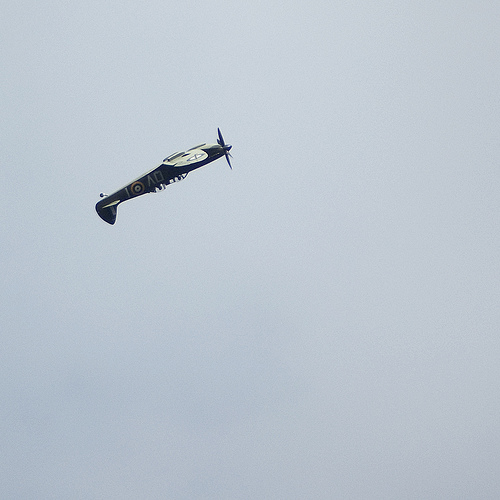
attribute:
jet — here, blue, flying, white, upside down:
[94, 125, 236, 226]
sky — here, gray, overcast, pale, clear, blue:
[2, 0, 500, 499]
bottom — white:
[163, 147, 209, 165]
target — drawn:
[130, 180, 144, 196]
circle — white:
[133, 184, 143, 192]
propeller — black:
[215, 125, 236, 172]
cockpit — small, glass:
[149, 172, 189, 194]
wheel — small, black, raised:
[99, 192, 105, 199]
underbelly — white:
[128, 141, 220, 189]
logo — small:
[186, 152, 204, 163]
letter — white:
[145, 173, 158, 189]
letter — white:
[152, 169, 166, 185]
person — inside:
[156, 183, 165, 191]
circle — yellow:
[130, 180, 146, 195]